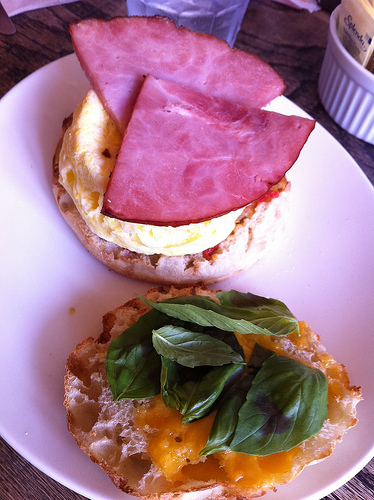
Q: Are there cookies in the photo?
A: No, there are no cookies.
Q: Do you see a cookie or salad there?
A: No, there are no cookies or salad.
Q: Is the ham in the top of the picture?
A: Yes, the ham is in the top of the image.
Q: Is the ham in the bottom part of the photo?
A: No, the ham is in the top of the image.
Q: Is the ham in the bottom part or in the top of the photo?
A: The ham is in the top of the image.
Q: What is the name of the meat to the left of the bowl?
A: The meat is ham.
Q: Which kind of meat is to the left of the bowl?
A: The meat is ham.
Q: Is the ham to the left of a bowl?
A: Yes, the ham is to the left of a bowl.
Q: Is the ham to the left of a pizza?
A: No, the ham is to the left of a bowl.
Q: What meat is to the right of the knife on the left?
A: The meat is ham.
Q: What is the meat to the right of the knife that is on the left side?
A: The meat is ham.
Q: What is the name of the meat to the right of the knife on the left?
A: The meat is ham.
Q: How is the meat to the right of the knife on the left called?
A: The meat is ham.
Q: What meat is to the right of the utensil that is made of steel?
A: The meat is ham.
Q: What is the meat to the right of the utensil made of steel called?
A: The meat is ham.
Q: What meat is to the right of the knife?
A: The meat is ham.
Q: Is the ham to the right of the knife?
A: Yes, the ham is to the right of the knife.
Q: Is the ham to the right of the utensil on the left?
A: Yes, the ham is to the right of the knife.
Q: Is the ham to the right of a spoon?
A: No, the ham is to the right of the knife.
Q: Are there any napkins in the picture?
A: No, there are no napkins.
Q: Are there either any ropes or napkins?
A: No, there are no napkins or ropes.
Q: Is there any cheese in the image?
A: Yes, there is cheese.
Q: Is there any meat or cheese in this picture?
A: Yes, there is cheese.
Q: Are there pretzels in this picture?
A: No, there are no pretzels.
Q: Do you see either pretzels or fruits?
A: No, there are no pretzels or fruits.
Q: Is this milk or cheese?
A: This is cheese.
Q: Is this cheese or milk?
A: This is cheese.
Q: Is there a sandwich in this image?
A: Yes, there is a sandwich.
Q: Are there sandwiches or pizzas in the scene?
A: Yes, there is a sandwich.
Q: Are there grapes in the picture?
A: No, there are no grapes.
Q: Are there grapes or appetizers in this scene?
A: No, there are no grapes or appetizers.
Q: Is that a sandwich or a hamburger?
A: That is a sandwich.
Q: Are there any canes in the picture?
A: No, there are no canes.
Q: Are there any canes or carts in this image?
A: No, there are no canes or carts.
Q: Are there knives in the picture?
A: Yes, there is a knife.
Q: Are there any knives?
A: Yes, there is a knife.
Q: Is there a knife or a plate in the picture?
A: Yes, there is a knife.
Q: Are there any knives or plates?
A: Yes, there is a knife.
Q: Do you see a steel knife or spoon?
A: Yes, there is a steel knife.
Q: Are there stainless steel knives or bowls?
A: Yes, there is a stainless steel knife.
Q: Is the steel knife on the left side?
A: Yes, the knife is on the left of the image.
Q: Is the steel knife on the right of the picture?
A: No, the knife is on the left of the image.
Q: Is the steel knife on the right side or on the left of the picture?
A: The knife is on the left of the image.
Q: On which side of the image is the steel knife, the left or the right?
A: The knife is on the left of the image.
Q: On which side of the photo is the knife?
A: The knife is on the left of the image.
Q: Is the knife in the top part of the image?
A: Yes, the knife is in the top of the image.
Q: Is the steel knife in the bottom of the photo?
A: No, the knife is in the top of the image.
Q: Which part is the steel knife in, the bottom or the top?
A: The knife is in the top of the image.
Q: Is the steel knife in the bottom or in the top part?
A: The knife is in the top of the image.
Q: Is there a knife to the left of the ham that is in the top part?
A: Yes, there is a knife to the left of the ham.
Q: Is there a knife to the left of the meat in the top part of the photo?
A: Yes, there is a knife to the left of the ham.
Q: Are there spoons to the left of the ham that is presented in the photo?
A: No, there is a knife to the left of the ham.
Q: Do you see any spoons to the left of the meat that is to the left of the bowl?
A: No, there is a knife to the left of the ham.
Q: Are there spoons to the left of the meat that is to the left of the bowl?
A: No, there is a knife to the left of the ham.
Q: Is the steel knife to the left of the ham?
A: Yes, the knife is to the left of the ham.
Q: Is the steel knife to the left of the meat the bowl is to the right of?
A: Yes, the knife is to the left of the ham.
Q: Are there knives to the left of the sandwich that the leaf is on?
A: Yes, there is a knife to the left of the sandwich.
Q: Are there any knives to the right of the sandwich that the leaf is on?
A: No, the knife is to the left of the sandwich.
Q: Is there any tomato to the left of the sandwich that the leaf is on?
A: No, there is a knife to the left of the sandwich.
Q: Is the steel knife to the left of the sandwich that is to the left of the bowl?
A: Yes, the knife is to the left of the sandwich.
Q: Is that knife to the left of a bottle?
A: No, the knife is to the left of the sandwich.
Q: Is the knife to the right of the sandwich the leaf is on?
A: No, the knife is to the left of the sandwich.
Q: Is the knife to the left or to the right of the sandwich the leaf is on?
A: The knife is to the left of the sandwich.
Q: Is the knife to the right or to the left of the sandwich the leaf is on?
A: The knife is to the left of the sandwich.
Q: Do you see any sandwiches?
A: Yes, there is a sandwich.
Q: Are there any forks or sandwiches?
A: Yes, there is a sandwich.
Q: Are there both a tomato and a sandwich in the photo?
A: No, there is a sandwich but no tomatoes.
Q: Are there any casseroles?
A: No, there are no casseroles.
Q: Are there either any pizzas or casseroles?
A: No, there are no casseroles or pizzas.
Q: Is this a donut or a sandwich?
A: This is a sandwich.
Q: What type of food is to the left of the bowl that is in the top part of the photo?
A: The food is a sandwich.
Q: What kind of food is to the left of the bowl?
A: The food is a sandwich.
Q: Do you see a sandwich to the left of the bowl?
A: Yes, there is a sandwich to the left of the bowl.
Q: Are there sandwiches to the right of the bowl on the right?
A: No, the sandwich is to the left of the bowl.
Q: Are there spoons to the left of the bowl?
A: No, there is a sandwich to the left of the bowl.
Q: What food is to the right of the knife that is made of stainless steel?
A: The food is a sandwich.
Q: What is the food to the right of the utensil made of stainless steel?
A: The food is a sandwich.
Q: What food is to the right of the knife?
A: The food is a sandwich.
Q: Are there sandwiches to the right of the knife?
A: Yes, there is a sandwich to the right of the knife.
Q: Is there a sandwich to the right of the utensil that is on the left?
A: Yes, there is a sandwich to the right of the knife.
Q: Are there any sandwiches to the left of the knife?
A: No, the sandwich is to the right of the knife.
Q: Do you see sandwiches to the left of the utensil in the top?
A: No, the sandwich is to the right of the knife.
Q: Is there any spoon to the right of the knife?
A: No, there is a sandwich to the right of the knife.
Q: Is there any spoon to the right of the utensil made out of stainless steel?
A: No, there is a sandwich to the right of the knife.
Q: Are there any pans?
A: No, there are no pans.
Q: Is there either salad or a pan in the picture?
A: No, there are no pans or salad.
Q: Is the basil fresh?
A: Yes, the basil is fresh.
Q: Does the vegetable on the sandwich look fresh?
A: Yes, the basil is fresh.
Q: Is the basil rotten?
A: No, the basil is fresh.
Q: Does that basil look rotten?
A: No, the basil is fresh.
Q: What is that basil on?
A: The basil is on the sandwich.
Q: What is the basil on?
A: The basil is on the sandwich.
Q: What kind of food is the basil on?
A: The basil is on the sandwich.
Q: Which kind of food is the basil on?
A: The basil is on the sandwich.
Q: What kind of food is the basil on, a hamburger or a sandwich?
A: The basil is on a sandwich.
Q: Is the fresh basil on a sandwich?
A: Yes, the basil is on a sandwich.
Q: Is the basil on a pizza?
A: No, the basil is on a sandwich.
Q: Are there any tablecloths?
A: No, there are no tablecloths.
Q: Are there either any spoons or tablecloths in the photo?
A: No, there are no tablecloths or spoons.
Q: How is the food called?
A: The food is a biscuit.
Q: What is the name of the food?
A: The food is a biscuit.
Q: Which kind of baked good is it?
A: The food is a biscuit.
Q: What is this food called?
A: This is a biscuit.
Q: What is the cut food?
A: The food is a biscuit.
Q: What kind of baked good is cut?
A: The baked good is a biscuit.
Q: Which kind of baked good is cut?
A: The baked good is a biscuit.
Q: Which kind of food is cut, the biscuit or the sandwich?
A: The biscuit is cut.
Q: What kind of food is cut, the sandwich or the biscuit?
A: The biscuit is cut.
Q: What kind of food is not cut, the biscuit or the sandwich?
A: The sandwich is not cut.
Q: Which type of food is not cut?
A: The food is a sandwich.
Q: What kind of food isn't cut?
A: The food is a sandwich.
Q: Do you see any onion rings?
A: No, there are no onion rings.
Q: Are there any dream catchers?
A: No, there are no dream catchers.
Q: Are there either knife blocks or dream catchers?
A: No, there are no dream catchers or knife blocks.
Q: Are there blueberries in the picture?
A: No, there are no blueberries.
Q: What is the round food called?
A: The food is an egg.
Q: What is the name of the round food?
A: The food is an egg.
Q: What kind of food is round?
A: The food is an egg.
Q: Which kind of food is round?
A: The food is an egg.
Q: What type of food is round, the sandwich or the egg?
A: The egg is round.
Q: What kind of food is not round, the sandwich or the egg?
A: The sandwich is not round.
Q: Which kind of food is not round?
A: The food is a sandwich.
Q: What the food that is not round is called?
A: The food is a sandwich.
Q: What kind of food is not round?
A: The food is a sandwich.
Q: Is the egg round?
A: Yes, the egg is round.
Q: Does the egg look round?
A: Yes, the egg is round.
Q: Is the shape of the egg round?
A: Yes, the egg is round.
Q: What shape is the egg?
A: The egg is round.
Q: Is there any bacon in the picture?
A: Yes, there is bacon.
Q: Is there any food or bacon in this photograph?
A: Yes, there is bacon.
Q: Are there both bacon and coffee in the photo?
A: No, there is bacon but no coffee.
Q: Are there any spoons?
A: No, there are no spoons.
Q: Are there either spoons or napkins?
A: No, there are no spoons or napkins.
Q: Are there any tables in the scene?
A: Yes, there is a table.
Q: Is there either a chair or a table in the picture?
A: Yes, there is a table.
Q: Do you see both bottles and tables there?
A: No, there is a table but no bottles.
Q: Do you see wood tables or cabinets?
A: Yes, there is a wood table.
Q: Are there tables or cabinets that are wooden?
A: Yes, the table is wooden.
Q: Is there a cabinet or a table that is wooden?
A: Yes, the table is wooden.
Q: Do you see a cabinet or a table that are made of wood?
A: Yes, the table is made of wood.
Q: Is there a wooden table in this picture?
A: Yes, there is a wood table.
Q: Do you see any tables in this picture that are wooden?
A: Yes, there is a table that is wooden.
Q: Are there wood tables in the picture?
A: Yes, there is a table that is made of wood.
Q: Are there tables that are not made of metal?
A: Yes, there is a table that is made of wood.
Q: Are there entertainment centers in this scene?
A: No, there are no entertainment centers.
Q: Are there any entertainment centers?
A: No, there are no entertainment centers.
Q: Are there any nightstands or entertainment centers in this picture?
A: No, there are no entertainment centers or nightstands.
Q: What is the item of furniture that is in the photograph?
A: The piece of furniture is a table.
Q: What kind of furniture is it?
A: The piece of furniture is a table.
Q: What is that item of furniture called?
A: That is a table.